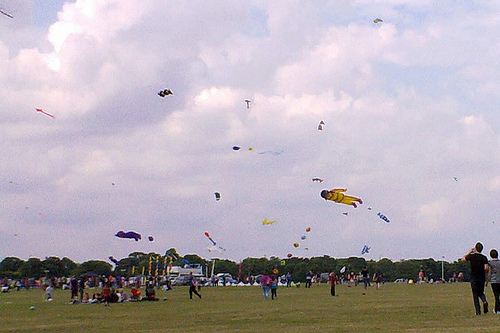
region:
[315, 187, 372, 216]
a man kite flying in the sky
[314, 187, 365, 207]
the man kite is yellow and black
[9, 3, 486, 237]
there are many kites flying in the sky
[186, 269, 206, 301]
a man is walking across the field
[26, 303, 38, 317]
a ball is on the ground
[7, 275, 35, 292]
a group of people are watching the kites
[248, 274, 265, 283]
a car is in the parking lot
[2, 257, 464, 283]
the trees are in the background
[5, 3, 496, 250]
the clouds are dark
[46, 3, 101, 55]
the sun is trying to break through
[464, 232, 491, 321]
man wearing a black shirt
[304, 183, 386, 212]
kite shaped like a superhero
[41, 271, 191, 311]
group of people gathered on grass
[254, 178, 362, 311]
people flying a kite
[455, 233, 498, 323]
couple watching kites in the sky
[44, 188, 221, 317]
group flying kites in a park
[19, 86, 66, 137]
red kite flying in the sky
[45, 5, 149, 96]
fluffy white clouds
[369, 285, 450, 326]
patch of green and brown grass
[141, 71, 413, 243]
multiple kites in the sky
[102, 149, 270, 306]
people outside flying kites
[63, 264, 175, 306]
people sitting on grass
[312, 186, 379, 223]
yellow kite in sky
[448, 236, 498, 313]
guy wearing black shirt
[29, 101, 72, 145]
red kite flying high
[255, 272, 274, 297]
person with purple shirt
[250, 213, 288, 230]
yellow kite in sky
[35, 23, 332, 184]
big white clouds and kites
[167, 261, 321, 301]
vehicles parked in distance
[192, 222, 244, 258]
blue and red kite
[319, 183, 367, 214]
a large yellow man kite in the sky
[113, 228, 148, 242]
a purple kite in the sky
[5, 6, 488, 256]
puffy white clouds in a blue sky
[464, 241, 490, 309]
a man looking up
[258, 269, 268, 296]
a person in a purple shirt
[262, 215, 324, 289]
a string of kites in the sky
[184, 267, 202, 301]
black pants on a person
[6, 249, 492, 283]
a green tree line behind the people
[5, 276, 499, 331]
a green grassy field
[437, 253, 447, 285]
a white pole in the field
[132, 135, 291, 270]
the sky is cloudy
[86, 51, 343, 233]
the sky is cloudy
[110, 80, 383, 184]
the sky is cloudy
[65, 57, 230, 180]
the sky is cloudy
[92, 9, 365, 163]
the sky is cloudy